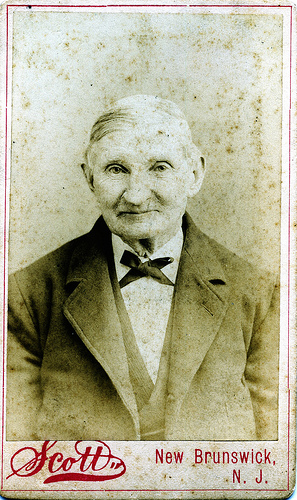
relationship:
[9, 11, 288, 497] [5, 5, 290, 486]
photo has border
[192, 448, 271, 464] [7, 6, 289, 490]
letter on sign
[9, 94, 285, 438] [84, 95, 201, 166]
man with grey hair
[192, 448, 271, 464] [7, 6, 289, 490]
letter on a sign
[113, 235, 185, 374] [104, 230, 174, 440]
shirt under vest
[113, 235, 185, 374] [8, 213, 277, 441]
shirt under coat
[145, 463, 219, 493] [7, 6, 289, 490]
rust spots on sign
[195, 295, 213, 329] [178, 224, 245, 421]
button hole on lapel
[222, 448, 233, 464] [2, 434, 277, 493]
letter on sign